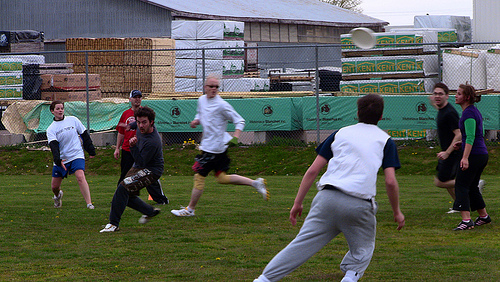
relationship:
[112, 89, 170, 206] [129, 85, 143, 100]
man wearing hat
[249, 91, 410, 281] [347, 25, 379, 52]
man plays with frisbee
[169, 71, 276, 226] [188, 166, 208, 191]
man wears brace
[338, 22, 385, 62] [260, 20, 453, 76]
frisbee in air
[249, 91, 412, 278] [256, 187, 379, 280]
man wearing sweatpants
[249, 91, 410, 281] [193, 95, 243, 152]
man wearing shirt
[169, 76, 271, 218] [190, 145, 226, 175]
man wearing black shorts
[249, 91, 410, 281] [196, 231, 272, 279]
man on grass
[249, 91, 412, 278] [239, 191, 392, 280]
man wearing sweat pants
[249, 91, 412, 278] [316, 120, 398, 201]
man wearing shirt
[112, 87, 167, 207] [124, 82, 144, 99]
man wearing hat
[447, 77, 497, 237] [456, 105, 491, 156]
girl wearing shirt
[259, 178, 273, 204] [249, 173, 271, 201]
bottom of shoe